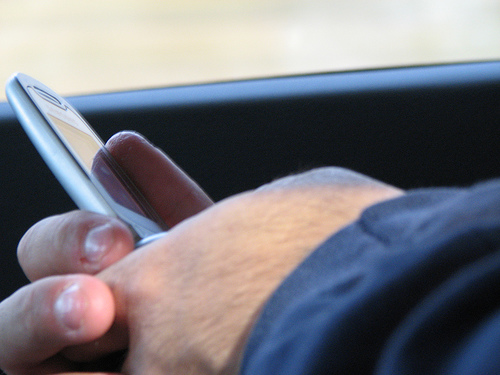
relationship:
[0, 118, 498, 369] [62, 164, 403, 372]
man has hand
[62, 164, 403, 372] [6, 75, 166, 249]
hand holding cellphone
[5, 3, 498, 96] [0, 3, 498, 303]
window on car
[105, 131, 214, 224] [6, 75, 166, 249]
finger touching cellphone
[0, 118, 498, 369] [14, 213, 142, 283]
man has finger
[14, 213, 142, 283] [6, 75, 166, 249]
finger holding cellphone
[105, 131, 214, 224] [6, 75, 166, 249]
finger holding cellphone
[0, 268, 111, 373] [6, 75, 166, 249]
finger holding cellphone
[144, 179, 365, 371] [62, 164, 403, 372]
hairy on hand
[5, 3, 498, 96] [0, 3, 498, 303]
window in car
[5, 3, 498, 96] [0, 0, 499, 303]
window has car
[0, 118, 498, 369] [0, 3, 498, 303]
man in car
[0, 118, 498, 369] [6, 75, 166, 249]
man looking at cellphone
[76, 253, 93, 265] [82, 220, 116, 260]
wound in fingernails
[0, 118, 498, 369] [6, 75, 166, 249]
man holding cellphone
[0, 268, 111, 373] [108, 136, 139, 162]
finger has skin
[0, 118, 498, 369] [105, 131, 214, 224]
man has finger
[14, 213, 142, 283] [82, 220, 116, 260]
finger has fingernails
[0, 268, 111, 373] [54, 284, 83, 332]
finger has fingernails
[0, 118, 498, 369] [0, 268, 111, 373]
man has finger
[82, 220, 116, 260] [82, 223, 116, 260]
fingernails has fingernails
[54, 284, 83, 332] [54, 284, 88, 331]
fingernails has fingernails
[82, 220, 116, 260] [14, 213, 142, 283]
fingernails in middle finger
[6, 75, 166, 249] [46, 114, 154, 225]
cellphone has screen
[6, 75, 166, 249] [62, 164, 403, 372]
cellphone on hand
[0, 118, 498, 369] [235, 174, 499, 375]
man wearing sleeve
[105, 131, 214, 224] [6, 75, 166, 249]
finger on side of cellphone